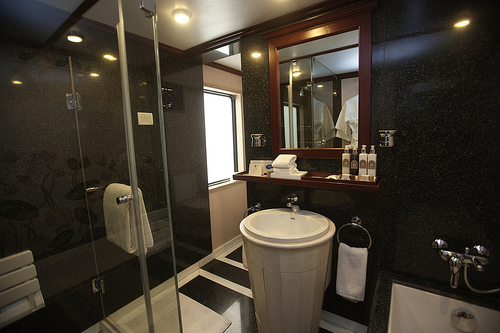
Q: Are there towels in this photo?
A: Yes, there is a towel.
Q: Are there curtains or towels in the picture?
A: Yes, there is a towel.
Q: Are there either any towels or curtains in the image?
A: Yes, there is a towel.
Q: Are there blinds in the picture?
A: No, there are no blinds.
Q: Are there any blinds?
A: No, there are no blinds.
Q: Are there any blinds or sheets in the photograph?
A: No, there are no blinds or sheets.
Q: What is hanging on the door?
A: The towel is hanging on the door.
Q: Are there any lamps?
A: No, there are no lamps.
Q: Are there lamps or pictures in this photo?
A: No, there are no lamps or pictures.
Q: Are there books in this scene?
A: No, there are no books.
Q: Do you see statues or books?
A: No, there are no books or statues.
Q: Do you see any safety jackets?
A: No, there are no safety jackets.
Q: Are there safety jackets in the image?
A: No, there are no safety jackets.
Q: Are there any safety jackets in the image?
A: No, there are no safety jackets.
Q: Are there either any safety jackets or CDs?
A: No, there are no safety jackets or cds.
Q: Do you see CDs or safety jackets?
A: No, there are no safety jackets or cds.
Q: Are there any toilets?
A: No, there are no toilets.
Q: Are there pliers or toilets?
A: No, there are no toilets or pliers.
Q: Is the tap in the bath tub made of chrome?
A: Yes, the faucet is made of chrome.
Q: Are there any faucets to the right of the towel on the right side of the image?
A: Yes, there is a faucet to the right of the towel.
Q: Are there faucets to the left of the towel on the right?
A: No, the faucet is to the right of the towel.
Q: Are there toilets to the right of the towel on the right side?
A: No, there is a faucet to the right of the towel.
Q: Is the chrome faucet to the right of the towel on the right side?
A: Yes, the tap is to the right of the towel.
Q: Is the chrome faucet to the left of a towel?
A: No, the faucet is to the right of a towel.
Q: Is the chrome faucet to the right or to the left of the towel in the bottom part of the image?
A: The faucet is to the right of the towel.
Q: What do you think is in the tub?
A: The tap is in the tub.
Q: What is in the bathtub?
A: The tap is in the tub.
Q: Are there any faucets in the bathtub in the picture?
A: Yes, there is a faucet in the bathtub.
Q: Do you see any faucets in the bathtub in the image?
A: Yes, there is a faucet in the bathtub.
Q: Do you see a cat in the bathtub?
A: No, there is a faucet in the bathtub.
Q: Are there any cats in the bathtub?
A: No, there is a faucet in the bathtub.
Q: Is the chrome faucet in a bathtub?
A: Yes, the tap is in a bathtub.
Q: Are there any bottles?
A: Yes, there is a bottle.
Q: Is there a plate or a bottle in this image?
A: Yes, there is a bottle.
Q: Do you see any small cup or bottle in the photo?
A: Yes, there is a small bottle.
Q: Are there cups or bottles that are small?
A: Yes, the bottle is small.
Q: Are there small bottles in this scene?
A: Yes, there is a small bottle.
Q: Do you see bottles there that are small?
A: Yes, there is a bottle that is small.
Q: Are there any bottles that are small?
A: Yes, there is a bottle that is small.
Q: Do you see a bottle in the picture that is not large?
A: Yes, there is a small bottle.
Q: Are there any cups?
A: No, there are no cups.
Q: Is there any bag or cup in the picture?
A: No, there are no cups or bags.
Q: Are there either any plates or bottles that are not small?
A: No, there is a bottle but it is small.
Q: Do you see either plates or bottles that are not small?
A: No, there is a bottle but it is small.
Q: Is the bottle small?
A: Yes, the bottle is small.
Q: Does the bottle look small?
A: Yes, the bottle is small.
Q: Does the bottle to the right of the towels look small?
A: Yes, the bottle is small.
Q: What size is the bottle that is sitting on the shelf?
A: The bottle is small.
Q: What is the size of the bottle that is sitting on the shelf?
A: The bottle is small.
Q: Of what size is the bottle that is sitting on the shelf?
A: The bottle is small.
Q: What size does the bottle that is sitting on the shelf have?
A: The bottle has small size.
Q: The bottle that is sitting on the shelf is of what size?
A: The bottle is small.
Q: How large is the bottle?
A: The bottle is small.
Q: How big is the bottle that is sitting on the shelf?
A: The bottle is small.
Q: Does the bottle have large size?
A: No, the bottle is small.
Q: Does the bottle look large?
A: No, the bottle is small.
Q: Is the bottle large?
A: No, the bottle is small.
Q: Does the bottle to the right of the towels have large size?
A: No, the bottle is small.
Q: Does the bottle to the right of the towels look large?
A: No, the bottle is small.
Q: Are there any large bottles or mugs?
A: No, there is a bottle but it is small.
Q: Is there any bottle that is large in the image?
A: No, there is a bottle but it is small.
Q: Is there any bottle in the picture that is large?
A: No, there is a bottle but it is small.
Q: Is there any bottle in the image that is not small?
A: No, there is a bottle but it is small.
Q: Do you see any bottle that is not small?
A: No, there is a bottle but it is small.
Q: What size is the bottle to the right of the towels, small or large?
A: The bottle is small.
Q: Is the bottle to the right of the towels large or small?
A: The bottle is small.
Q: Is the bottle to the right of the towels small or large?
A: The bottle is small.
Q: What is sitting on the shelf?
A: The bottle is sitting on the shelf.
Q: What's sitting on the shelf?
A: The bottle is sitting on the shelf.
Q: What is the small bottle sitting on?
A: The bottle is sitting on the shelf.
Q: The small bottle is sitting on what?
A: The bottle is sitting on the shelf.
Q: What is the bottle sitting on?
A: The bottle is sitting on the shelf.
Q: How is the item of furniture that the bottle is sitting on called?
A: The piece of furniture is a shelf.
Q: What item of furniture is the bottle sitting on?
A: The bottle is sitting on the shelf.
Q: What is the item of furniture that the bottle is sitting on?
A: The piece of furniture is a shelf.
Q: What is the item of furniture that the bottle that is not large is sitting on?
A: The piece of furniture is a shelf.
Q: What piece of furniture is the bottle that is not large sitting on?
A: The bottle is sitting on the shelf.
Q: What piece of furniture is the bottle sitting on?
A: The bottle is sitting on the shelf.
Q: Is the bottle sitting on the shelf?
A: Yes, the bottle is sitting on the shelf.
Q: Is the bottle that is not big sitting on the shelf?
A: Yes, the bottle is sitting on the shelf.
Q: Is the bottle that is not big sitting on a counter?
A: No, the bottle is sitting on the shelf.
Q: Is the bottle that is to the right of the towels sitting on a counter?
A: No, the bottle is sitting on the shelf.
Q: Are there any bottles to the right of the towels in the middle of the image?
A: Yes, there is a bottle to the right of the towels.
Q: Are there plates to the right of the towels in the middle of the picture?
A: No, there is a bottle to the right of the towels.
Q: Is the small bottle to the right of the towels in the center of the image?
A: Yes, the bottle is to the right of the towels.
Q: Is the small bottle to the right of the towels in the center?
A: Yes, the bottle is to the right of the towels.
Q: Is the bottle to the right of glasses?
A: No, the bottle is to the right of the towels.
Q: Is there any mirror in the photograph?
A: Yes, there is a mirror.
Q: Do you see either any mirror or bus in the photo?
A: Yes, there is a mirror.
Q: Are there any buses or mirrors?
A: Yes, there is a mirror.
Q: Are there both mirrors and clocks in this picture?
A: No, there is a mirror but no clocks.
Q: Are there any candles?
A: No, there are no candles.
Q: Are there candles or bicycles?
A: No, there are no candles or bicycles.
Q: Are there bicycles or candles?
A: No, there are no candles or bicycles.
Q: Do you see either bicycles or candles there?
A: No, there are no candles or bicycles.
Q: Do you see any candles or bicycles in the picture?
A: No, there are no candles or bicycles.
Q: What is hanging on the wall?
A: The mirror is hanging on the wall.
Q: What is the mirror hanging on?
A: The mirror is hanging on the wall.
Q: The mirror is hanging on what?
A: The mirror is hanging on the wall.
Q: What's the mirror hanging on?
A: The mirror is hanging on the wall.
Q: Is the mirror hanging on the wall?
A: Yes, the mirror is hanging on the wall.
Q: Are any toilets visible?
A: No, there are no toilets.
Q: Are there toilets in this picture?
A: No, there are no toilets.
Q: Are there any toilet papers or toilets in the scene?
A: No, there are no toilets or toilet papers.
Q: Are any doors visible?
A: Yes, there is a door.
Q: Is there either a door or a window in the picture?
A: Yes, there is a door.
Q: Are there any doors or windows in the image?
A: Yes, there is a door.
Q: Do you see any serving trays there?
A: No, there are no serving trays.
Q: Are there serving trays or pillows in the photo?
A: No, there are no serving trays or pillows.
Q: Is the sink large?
A: Yes, the sink is large.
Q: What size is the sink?
A: The sink is large.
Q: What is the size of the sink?
A: The sink is large.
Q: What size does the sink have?
A: The sink has large size.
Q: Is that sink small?
A: No, the sink is large.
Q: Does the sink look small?
A: No, the sink is large.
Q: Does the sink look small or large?
A: The sink is large.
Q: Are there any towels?
A: Yes, there is a towel.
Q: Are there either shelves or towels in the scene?
A: Yes, there is a towel.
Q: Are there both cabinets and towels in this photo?
A: No, there is a towel but no cabinets.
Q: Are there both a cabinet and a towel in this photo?
A: No, there is a towel but no cabinets.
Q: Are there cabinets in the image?
A: No, there are no cabinets.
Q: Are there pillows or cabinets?
A: No, there are no cabinets or pillows.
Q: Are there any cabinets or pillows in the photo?
A: No, there are no cabinets or pillows.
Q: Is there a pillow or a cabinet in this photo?
A: No, there are no cabinets or pillows.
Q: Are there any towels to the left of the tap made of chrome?
A: Yes, there is a towel to the left of the faucet.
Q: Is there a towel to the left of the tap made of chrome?
A: Yes, there is a towel to the left of the faucet.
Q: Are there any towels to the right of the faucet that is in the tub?
A: No, the towel is to the left of the faucet.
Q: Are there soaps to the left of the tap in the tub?
A: No, there is a towel to the left of the tap.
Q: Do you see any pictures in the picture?
A: No, there are no pictures.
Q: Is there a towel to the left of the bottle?
A: Yes, there are towels to the left of the bottle.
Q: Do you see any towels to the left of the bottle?
A: Yes, there are towels to the left of the bottle.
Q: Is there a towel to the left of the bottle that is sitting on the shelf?
A: Yes, there are towels to the left of the bottle.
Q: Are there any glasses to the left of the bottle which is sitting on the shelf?
A: No, there are towels to the left of the bottle.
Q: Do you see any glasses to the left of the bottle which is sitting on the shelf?
A: No, there are towels to the left of the bottle.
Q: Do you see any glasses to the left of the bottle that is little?
A: No, there are towels to the left of the bottle.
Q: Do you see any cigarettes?
A: No, there are no cigarettes.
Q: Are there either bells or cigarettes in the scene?
A: No, there are no cigarettes or bells.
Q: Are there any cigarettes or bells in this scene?
A: No, there are no cigarettes or bells.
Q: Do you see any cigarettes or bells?
A: No, there are no cigarettes or bells.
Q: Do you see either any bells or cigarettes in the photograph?
A: No, there are no cigarettes or bells.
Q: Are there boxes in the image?
A: No, there are no boxes.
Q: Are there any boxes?
A: No, there are no boxes.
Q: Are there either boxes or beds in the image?
A: No, there are no boxes or beds.